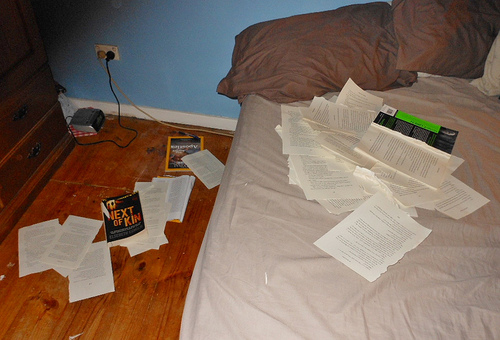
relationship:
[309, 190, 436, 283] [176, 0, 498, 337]
paper on bed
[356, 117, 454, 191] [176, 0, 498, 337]
paper on bed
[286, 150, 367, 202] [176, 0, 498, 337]
paper on bed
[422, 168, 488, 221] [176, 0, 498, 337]
paper on bed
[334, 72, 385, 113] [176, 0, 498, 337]
paper on bed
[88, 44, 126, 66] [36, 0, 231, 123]
socket on wall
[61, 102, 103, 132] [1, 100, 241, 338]
alarm clock on floor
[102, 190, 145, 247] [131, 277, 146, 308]
book on floor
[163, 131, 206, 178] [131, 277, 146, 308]
book on floor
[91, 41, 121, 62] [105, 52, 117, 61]
socket with plug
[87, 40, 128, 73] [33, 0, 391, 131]
power socket in wall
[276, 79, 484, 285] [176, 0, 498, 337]
book torn on bed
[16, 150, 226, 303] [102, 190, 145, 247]
pages of book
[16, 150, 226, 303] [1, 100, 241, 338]
pages on floor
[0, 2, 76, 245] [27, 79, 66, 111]
chest of drawer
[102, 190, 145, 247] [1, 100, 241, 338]
book on floor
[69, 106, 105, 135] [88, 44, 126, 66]
radio connected to socket